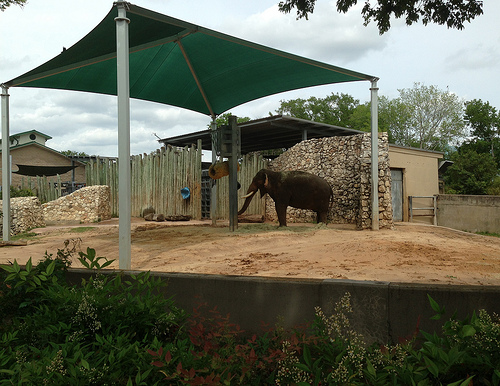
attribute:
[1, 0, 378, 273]
canopy — green 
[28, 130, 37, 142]
window — circular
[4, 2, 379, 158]
awning — green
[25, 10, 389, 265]
shading — high, canvas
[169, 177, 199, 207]
bucket — blue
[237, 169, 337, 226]
elephant — Small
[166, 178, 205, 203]
bucket — blue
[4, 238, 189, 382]
bush — green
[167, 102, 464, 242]
building — small 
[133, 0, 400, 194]
canopy — green 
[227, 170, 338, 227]
elephant — brown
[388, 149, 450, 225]
building — small 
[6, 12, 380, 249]
tent — green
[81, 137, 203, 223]
fence — wooden 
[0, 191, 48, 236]
wall — low, stone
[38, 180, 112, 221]
wall — low, stone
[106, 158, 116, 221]
tree limb — uneven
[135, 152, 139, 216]
tree limb — uneven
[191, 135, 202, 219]
tree limb — uneven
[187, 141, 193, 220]
tree limb — uneven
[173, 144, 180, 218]
tree limb — uneven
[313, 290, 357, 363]
shrub — decorative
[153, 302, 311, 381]
shrub — decorative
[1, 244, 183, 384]
shrub — decorative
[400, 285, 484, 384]
shrub — decorative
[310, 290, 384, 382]
shrub — decorative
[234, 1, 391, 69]
cloud — low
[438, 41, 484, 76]
cloud — low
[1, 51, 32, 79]
cloud — low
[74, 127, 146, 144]
cloud — low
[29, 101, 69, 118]
cloud — low